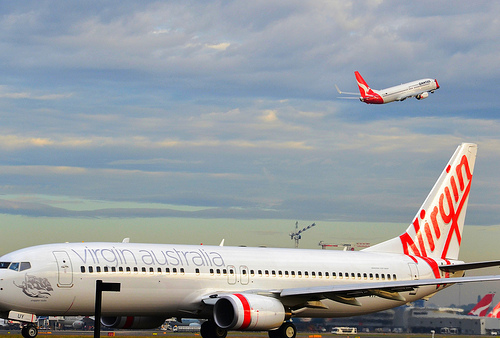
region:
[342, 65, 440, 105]
aircraft taking off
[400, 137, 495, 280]
Tail section of a Virgin Airlines plane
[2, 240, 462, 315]
airplane fuselage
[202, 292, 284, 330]
jet engine painted white with red circular stripe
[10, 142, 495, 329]
Virgin Airlines plane on the ground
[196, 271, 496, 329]
airplane wing with one engine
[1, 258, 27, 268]
airplane cockpit windows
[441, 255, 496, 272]
airplane horizontal stabilizer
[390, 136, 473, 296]
Virgin Airlines logo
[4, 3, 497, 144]
airplane taking off into a cloudy sky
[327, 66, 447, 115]
This is an airplane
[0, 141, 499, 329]
This is an airplane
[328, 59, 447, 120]
This is a red and white airplane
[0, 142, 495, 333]
This is a red and white airplane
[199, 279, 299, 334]
This is the left fuselage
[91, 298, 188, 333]
This is the right fuselage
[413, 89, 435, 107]
This is the right fuselage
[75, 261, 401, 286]
Windows of an airplane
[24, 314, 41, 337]
Front wheel of an airplane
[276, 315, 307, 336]
Behind wheel of an airplane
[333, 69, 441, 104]
the airplane in the sky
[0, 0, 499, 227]
the clouds in the sky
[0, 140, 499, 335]
the airplane on the ground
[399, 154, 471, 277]
the word Virgin on the tail of the plane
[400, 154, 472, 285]
the word Virgin written in red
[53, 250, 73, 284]
the door to the airplane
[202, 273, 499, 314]
the wing of the airplane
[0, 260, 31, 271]
the windows to the cockpit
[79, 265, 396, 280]
the passenger windows on the airplane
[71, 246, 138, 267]
the word virgin on the plane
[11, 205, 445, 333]
white airliner sitting on tarmac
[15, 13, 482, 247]
white clouds in sky overhead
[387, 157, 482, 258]
red virgin sign on plane's tail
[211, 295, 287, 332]
red and white engine under wing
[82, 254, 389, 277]
row of passenger windows on plane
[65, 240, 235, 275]
virgin australia logo on plane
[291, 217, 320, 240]
large crane off in the distance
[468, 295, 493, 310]
tails of red planes on the right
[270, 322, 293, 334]
black tires under plane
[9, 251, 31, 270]
cockpit in front of the plane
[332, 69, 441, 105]
plane taking off into sky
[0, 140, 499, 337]
white plane on ground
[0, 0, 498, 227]
clouds in sky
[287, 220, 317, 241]
black and white striped post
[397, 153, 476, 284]
red writing on tail fin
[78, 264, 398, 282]
side windows of plane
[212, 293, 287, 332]
left engine of plane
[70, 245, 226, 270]
grey writing on side of plane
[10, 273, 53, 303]
grey picture on side of plane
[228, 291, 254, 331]
red stripe around engine